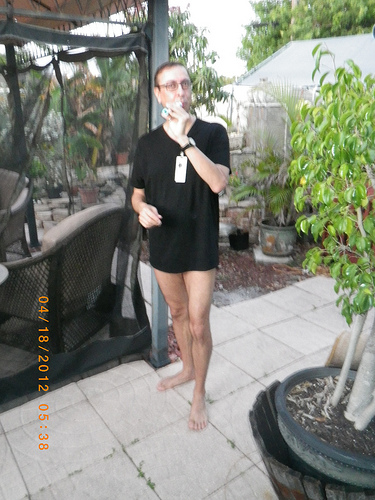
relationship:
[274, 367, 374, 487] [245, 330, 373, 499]
pot sitting inside a barrel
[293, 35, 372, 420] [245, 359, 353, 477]
tree growing in pot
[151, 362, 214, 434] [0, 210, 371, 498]
feet on ground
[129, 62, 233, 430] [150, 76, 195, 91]
man wearing glasses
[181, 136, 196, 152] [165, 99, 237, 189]
watch on arm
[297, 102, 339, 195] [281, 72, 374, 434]
green leaves on plant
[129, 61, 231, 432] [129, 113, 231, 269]
man wearing t shirt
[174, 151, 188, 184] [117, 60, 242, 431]
badge on man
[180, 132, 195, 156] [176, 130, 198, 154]
watch on wrist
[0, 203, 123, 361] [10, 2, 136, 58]
chair under awning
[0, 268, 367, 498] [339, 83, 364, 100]
tiles on ground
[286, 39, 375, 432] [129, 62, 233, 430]
tree beside man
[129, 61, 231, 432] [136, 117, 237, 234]
man wearing shirt